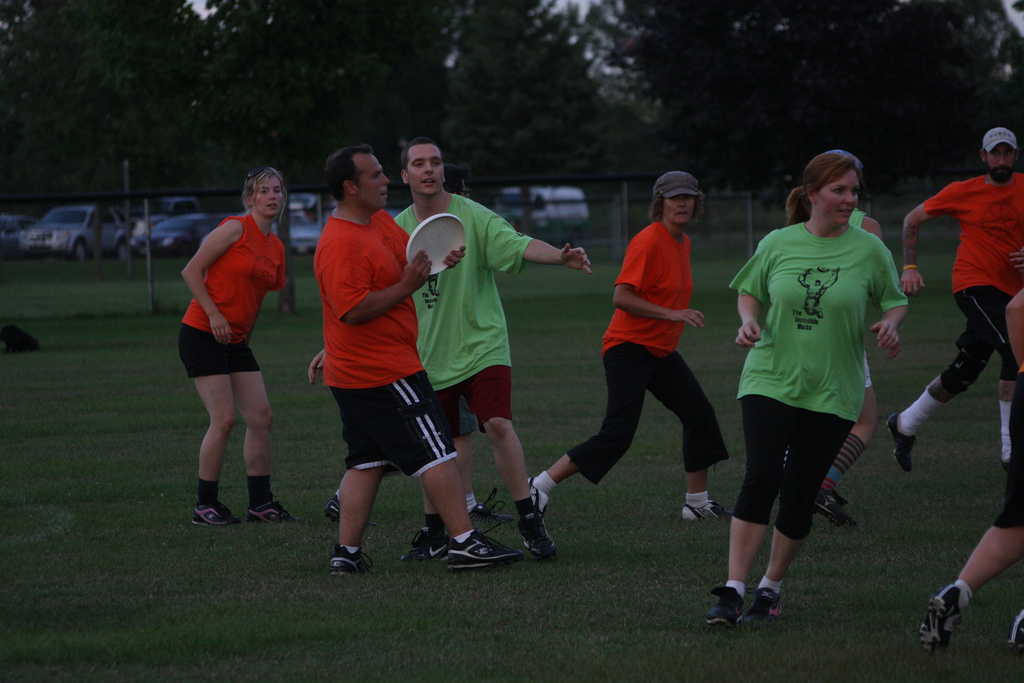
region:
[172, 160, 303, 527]
a person is playing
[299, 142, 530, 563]
a person is playing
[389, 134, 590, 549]
a person is playing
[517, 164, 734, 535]
a person is playing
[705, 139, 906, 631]
a person is playing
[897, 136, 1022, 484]
a person is playing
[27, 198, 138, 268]
a car in a parking lot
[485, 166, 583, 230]
a car in a parking lot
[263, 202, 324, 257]
a car in a parking lot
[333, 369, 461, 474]
the shorts are black and white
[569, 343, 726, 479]
the pants are black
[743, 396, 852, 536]
some tight black pants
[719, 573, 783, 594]
the socks are white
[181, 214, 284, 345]
the shirt is orange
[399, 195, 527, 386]
the shirt is green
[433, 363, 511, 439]
the shorts are red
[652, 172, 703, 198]
the hat is gray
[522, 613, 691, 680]
a view of grass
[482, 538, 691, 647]
a view of ground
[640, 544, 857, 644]
shoes of the person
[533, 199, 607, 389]
hand of the person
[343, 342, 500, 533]
lines in the shorts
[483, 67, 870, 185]
a view of plants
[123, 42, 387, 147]
a view of leafs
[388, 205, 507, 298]
frisbee is white in color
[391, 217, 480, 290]
man holding a frisbee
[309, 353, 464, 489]
man wearing black shorts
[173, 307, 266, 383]
woman wearing black shorts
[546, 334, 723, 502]
woman wearing black pants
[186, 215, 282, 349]
woman wearing a orange tee shirt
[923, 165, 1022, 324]
man wearing a orange tee shirt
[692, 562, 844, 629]
woman wearing black shoes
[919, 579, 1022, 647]
woman wearing black shoes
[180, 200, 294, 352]
orange shirt worn by woman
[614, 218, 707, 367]
orange shirt worn by woman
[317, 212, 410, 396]
orange shirt worn by man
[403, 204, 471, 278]
white Frisbee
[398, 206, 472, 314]
white Frisbee held by man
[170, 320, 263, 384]
black shorts worn by woman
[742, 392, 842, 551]
black capris worn by woman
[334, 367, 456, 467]
black shorts worn by man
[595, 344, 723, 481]
black pants worn by woman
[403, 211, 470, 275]
A round white frisbee.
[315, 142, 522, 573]
Dark haired man in orange holding a frisbee.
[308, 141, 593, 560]
Man in green shirt and red shorts.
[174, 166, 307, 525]
Woman with one arm in an orange shirt.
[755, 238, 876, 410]
The shirt is lime green.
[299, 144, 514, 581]
player wearing an orange colored shirt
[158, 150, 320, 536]
player wearing an orange colored shirt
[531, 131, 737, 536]
player wearing an orange colored shirt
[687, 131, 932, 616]
player wearing a green colored shirt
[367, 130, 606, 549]
player wearing a green colored shirt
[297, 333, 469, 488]
black colored shorts of the player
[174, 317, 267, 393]
black colored shorts of the player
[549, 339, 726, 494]
black colored shorts of the player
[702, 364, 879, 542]
black colored shorts of the player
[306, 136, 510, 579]
A person is playing.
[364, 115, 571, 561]
A person is playing.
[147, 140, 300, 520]
A person is playing.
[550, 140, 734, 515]
A person is playing.